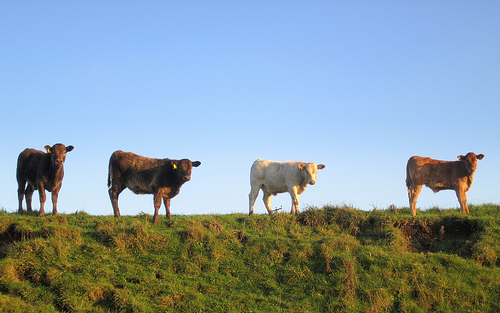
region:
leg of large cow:
[11, 173, 28, 213]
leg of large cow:
[23, 177, 41, 213]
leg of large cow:
[31, 179, 50, 216]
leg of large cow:
[43, 183, 65, 217]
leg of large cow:
[94, 173, 135, 224]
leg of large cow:
[143, 189, 167, 226]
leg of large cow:
[159, 195, 186, 230]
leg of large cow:
[238, 173, 262, 221]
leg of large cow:
[257, 182, 279, 224]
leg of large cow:
[285, 178, 308, 217]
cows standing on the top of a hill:
[10, 139, 494, 210]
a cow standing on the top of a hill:
[15, 142, 74, 214]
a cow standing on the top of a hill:
[100, 151, 200, 220]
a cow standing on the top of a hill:
[245, 156, 322, 214]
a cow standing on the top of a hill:
[400, 150, 482, 215]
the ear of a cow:
[475, 150, 486, 162]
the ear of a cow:
[455, 151, 463, 162]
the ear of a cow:
[315, 160, 326, 170]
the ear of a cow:
[191, 157, 201, 167]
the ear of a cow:
[64, 140, 74, 153]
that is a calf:
[12, 143, 76, 208]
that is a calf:
[102, 131, 199, 223]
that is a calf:
[252, 158, 323, 209]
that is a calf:
[400, 153, 478, 213]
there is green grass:
[32, 241, 62, 268]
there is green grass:
[140, 249, 190, 280]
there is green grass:
[211, 275, 312, 295]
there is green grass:
[205, 238, 315, 260]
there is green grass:
[327, 259, 421, 290]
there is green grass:
[111, 236, 298, 267]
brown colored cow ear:
[43, 144, 53, 153]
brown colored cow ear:
[66, 143, 76, 153]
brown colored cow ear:
[163, 156, 174, 167]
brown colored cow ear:
[188, 157, 203, 168]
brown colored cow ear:
[295, 159, 304, 173]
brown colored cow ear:
[313, 158, 325, 170]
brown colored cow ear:
[454, 153, 466, 161]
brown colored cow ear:
[477, 151, 486, 163]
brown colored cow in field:
[15, 134, 78, 217]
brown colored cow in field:
[103, 152, 205, 221]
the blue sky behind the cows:
[5, 5, 495, 120]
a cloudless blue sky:
[6, 4, 490, 107]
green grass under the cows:
[21, 211, 443, 311]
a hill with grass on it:
[33, 216, 442, 296]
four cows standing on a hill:
[13, 141, 482, 310]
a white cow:
[248, 164, 326, 211]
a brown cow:
[401, 153, 479, 213]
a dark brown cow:
[100, 148, 197, 217]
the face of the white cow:
[301, 157, 318, 182]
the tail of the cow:
[104, 161, 116, 183]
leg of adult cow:
[15, 178, 26, 210]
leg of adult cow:
[22, 183, 35, 211]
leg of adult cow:
[35, 180, 48, 216]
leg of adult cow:
[48, 190, 60, 217]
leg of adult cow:
[108, 183, 122, 216]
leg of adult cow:
[152, 190, 159, 224]